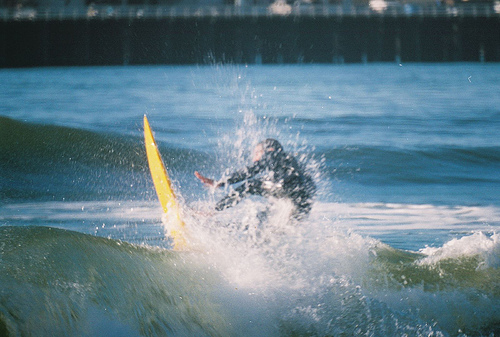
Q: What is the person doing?
A: Surfing.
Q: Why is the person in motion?
A: They are surfing.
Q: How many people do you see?
A: One.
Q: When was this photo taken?
A: During the day.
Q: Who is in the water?
A: A surfer.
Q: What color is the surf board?
A: Yellow.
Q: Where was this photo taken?
A: In the water.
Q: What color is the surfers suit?
A: Black.